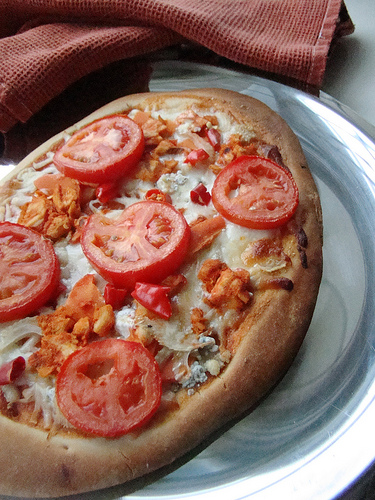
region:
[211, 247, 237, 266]
White cheese melted on pizza.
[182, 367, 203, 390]
Blue cheese on top of pizza.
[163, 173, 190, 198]
Blue cheese on top of pizza.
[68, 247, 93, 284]
White cheese melted on top of pizza.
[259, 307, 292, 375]
Golden brown crust on pizza.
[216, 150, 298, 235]
tomato on the pizza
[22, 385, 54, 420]
cheese on the pizza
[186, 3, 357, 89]
a handcloth for the hot plate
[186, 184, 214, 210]
red pepper on the pizza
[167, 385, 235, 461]
the pizza crust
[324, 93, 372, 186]
edge of the plate the pizza is on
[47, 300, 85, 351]
meat topping on the pizza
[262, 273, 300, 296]
burnt cheese on the crust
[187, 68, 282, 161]
edge of the pizza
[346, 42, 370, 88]
a gray table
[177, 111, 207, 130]
brown colored pizza topping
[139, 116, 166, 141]
brown colored pizza topping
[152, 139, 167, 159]
brown colored pizza topping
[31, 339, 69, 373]
brown colored pizza topping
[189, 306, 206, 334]
brown colored pizza topping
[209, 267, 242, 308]
brown colored pizza topping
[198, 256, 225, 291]
brown colored pizza topping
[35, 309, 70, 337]
brown colored pizza topping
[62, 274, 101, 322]
brown colored pizza topping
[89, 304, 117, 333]
brown colored pizza topping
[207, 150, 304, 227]
slice of red tomato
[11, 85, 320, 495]
pizza crust with toppings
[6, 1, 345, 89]
rust colored cloth napkin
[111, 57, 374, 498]
pizza on a silver plate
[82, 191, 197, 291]
tomato slice with seeds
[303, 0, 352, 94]
trim on a piece of cloth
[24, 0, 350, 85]
folded cloth with large weave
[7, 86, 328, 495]
pizza with golden brown crust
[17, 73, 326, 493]
variety of toppings on pizza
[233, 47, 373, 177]
edge of round silver plate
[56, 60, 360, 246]
pizza is on the tray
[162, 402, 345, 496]
the tray is silver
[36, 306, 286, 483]
tomatoes are on the pizza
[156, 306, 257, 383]
the cheese is white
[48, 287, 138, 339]
bacon is on the pizza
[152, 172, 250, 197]
feta cheese is on the pizza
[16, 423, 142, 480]
the crust is brown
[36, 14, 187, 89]
a towel is by the pizza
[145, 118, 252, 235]
diced peppers on the pizza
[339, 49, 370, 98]
the table is gray